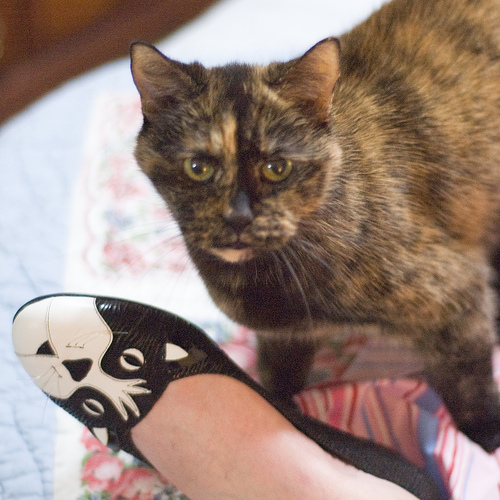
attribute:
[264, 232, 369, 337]
whiskers — white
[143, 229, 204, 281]
whiskers — white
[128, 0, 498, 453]
brown cat — dark brown, tan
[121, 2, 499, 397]
cat — black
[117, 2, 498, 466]
cat — brown, real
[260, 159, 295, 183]
eye — yellow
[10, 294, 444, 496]
shoe — black, white 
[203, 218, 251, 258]
mouth — brown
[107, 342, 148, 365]
eye — white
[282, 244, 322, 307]
whisker — long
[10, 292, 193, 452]
shoe — black, white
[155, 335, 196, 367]
ear — white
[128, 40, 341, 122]
ears — black, brown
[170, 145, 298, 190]
eyes — black, white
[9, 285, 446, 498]
cat shoe — white , black 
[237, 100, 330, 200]
fur — different color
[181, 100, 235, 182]
fur — different color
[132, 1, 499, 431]
cat — real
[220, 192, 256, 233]
nose — small